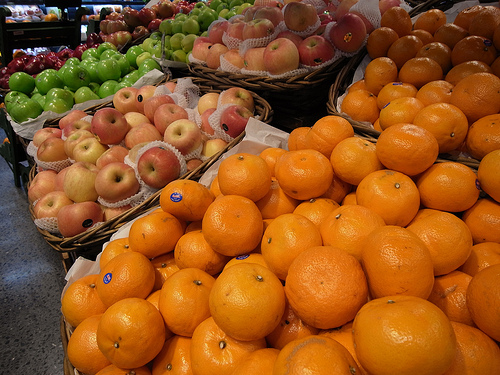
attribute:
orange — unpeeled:
[255, 210, 330, 262]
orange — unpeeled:
[160, 276, 216, 342]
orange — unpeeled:
[112, 300, 167, 369]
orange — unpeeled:
[350, 289, 444, 369]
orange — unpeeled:
[371, 130, 430, 216]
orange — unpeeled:
[211, 151, 271, 211]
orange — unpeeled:
[97, 300, 167, 369]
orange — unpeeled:
[225, 134, 492, 324]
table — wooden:
[1, 20, 82, 65]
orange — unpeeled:
[202, 103, 408, 278]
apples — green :
[192, 139, 408, 372]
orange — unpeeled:
[278, 242, 362, 332]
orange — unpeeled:
[351, 294, 463, 374]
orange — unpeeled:
[375, 118, 452, 175]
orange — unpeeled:
[276, 150, 342, 203]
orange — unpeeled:
[198, 191, 278, 257]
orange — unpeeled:
[184, 176, 402, 320]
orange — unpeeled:
[204, 193, 264, 256]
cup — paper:
[97, 191, 154, 208]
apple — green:
[221, 105, 251, 134]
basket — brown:
[29, 70, 279, 271]